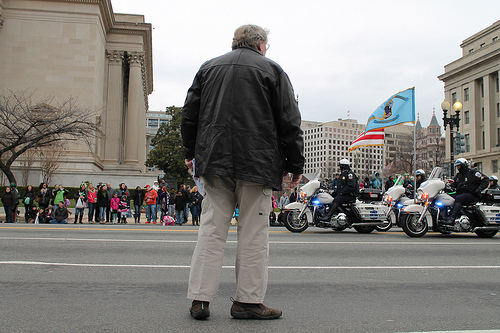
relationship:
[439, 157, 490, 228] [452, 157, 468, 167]
cop wearing helmet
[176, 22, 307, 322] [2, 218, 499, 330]
man in street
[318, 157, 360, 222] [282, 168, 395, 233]
man riding a motorcycle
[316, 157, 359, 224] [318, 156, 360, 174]
man wearing helmet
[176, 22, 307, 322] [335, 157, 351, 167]
man wearing helmet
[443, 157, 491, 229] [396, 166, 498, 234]
cop riding a motorcycle